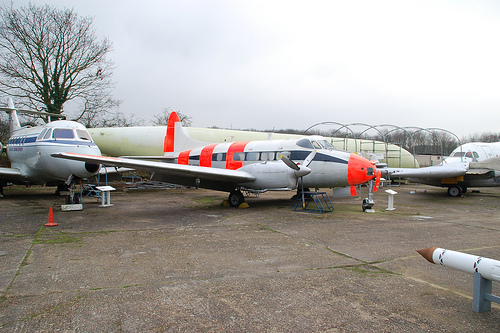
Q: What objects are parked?
A: Planes.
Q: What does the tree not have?
A: Leaves.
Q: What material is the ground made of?
A: Concrete pavement.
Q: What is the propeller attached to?
A: Wing.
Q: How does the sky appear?
A: Overcast.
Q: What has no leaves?
A: A tree.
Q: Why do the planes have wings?
A: To fly.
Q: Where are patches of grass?
A: On the ground.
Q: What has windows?
A: The planes.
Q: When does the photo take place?
A: During the daytime.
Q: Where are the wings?
A: On sides of the planes.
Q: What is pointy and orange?
A: Traffic cone.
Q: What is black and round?
A: Wheels.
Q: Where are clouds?
A: In the sky.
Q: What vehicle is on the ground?
A: Jet.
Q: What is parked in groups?
A: Jets.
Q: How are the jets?
A: Parked.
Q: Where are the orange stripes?
A: On the jet.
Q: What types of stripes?
A: Orange.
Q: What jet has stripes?
A: The middle jet.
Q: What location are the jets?
A: Airport.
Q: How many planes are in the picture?
A: Four.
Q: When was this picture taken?
A: During the day.